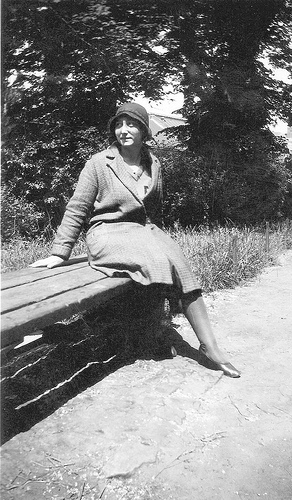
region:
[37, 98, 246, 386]
a woman on a bench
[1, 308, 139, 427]
shadow from the bench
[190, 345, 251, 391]
a shiny shoe on foot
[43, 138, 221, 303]
a long jacket on woman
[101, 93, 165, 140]
a hat on her head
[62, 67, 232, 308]
a woman in coat and hat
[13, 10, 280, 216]
two big trees behind woman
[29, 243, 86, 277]
a hand on the bench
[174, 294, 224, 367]
stockings on her legs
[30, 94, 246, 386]
woman sit on bench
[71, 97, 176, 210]
woman has black hat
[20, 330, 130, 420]
a shadow on the cast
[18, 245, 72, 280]
hand over a bench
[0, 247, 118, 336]
a bench is made wood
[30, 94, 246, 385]
woman wears a coat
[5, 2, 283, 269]
woman in front the trees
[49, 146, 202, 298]
the coat is long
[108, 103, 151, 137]
grey hat on head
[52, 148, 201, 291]
wool trench coat jacket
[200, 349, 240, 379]
shiny flat ballet shoes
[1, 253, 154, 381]
wooden backless park bench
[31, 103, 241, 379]
woman sitting on bench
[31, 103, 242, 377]
woman wearing hat in park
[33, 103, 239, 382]
woman sitting in park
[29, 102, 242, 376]
woman wearing trench coat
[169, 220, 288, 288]
grass next to sidewalk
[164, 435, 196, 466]
a crack on ground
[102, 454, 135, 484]
a crack on ground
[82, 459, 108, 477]
a crack on ground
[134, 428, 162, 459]
a crack on ground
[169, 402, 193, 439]
a crack on ground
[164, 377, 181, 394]
a crack on ground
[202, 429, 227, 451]
a crack on ground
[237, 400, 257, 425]
a crack on ground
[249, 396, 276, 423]
a crack on ground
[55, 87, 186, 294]
lady sitting on a bench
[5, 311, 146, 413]
shadow of a wooden bench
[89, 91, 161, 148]
woman wearing a hat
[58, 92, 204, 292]
woman with long winter jacket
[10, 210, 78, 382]
the top of a wooden bench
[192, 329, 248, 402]
a foot wearing a flat shoe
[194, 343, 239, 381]
flat shiny shoe on concrete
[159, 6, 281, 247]
trees and grass in black and white